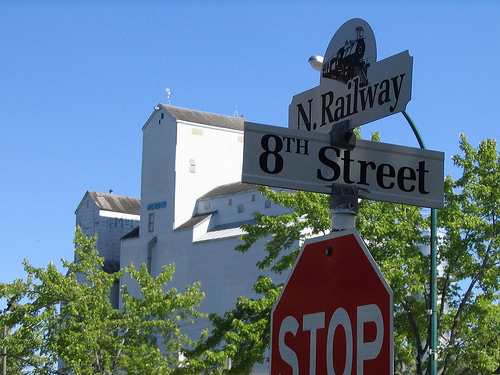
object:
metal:
[324, 245, 334, 258]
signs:
[240, 18, 444, 206]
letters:
[260, 133, 431, 196]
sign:
[267, 230, 395, 374]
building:
[74, 102, 458, 374]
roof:
[158, 102, 245, 130]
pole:
[400, 111, 439, 372]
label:
[146, 200, 168, 211]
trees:
[0, 232, 268, 373]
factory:
[63, 102, 459, 375]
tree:
[0, 132, 499, 375]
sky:
[0, 0, 499, 108]